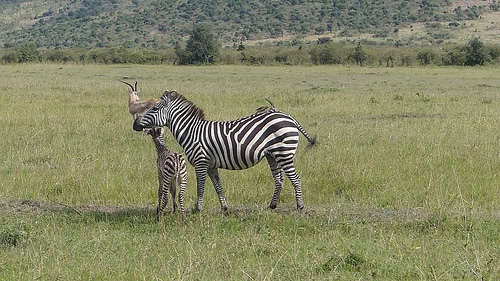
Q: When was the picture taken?
A: Morning.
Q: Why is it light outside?
A: Sun.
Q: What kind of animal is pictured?
A: Zebra.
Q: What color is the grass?
A: Green.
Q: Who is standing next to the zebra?
A: Nobody.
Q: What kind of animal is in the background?
A: Antelope.